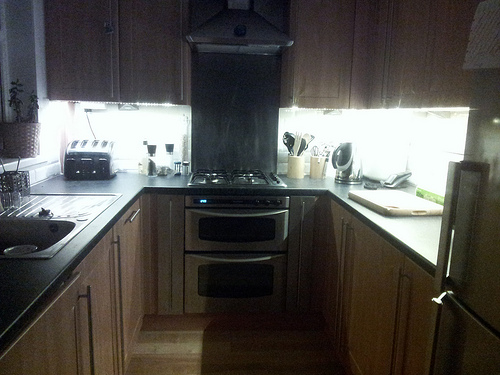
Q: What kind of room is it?
A: It is a kitchen.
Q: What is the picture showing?
A: It is showing a kitchen.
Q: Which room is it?
A: It is a kitchen.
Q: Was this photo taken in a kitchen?
A: Yes, it was taken in a kitchen.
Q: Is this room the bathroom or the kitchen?
A: It is the kitchen.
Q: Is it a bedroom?
A: No, it is a kitchen.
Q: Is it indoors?
A: Yes, it is indoors.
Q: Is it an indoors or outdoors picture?
A: It is indoors.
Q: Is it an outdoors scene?
A: No, it is indoors.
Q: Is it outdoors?
A: No, it is indoors.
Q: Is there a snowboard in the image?
A: No, there are no snowboards.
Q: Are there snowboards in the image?
A: No, there are no snowboards.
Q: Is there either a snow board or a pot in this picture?
A: No, there are no snowboards or pots.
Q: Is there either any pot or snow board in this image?
A: No, there are no snowboards or pots.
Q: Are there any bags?
A: No, there are no bags.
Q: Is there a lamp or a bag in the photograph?
A: No, there are no bags or lamps.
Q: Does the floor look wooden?
A: Yes, the floor is wooden.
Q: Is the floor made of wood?
A: Yes, the floor is made of wood.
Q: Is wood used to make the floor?
A: Yes, the floor is made of wood.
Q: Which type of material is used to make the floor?
A: The floor is made of wood.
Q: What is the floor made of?
A: The floor is made of wood.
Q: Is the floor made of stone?
A: No, the floor is made of wood.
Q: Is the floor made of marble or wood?
A: The floor is made of wood.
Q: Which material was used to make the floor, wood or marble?
A: The floor is made of wood.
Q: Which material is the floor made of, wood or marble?
A: The floor is made of wood.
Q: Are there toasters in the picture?
A: Yes, there is a toaster.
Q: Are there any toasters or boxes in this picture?
A: Yes, there is a toaster.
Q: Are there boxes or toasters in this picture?
A: Yes, there is a toaster.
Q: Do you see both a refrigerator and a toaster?
A: Yes, there are both a toaster and a refrigerator.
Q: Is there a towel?
A: No, there are no towels.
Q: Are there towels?
A: No, there are no towels.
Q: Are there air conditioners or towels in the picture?
A: No, there are no towels or air conditioners.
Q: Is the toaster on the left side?
A: Yes, the toaster is on the left of the image.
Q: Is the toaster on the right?
A: No, the toaster is on the left of the image.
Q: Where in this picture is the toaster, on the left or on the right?
A: The toaster is on the left of the image.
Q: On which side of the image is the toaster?
A: The toaster is on the left of the image.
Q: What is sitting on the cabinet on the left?
A: The toaster is sitting on the cabinet.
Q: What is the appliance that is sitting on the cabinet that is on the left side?
A: The appliance is a toaster.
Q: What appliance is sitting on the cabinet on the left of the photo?
A: The appliance is a toaster.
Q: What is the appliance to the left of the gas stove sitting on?
A: The toaster is sitting on the cabinet.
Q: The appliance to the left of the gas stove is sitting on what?
A: The toaster is sitting on the cabinet.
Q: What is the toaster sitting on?
A: The toaster is sitting on the cabinet.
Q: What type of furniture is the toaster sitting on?
A: The toaster is sitting on the cabinet.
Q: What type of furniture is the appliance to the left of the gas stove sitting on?
A: The toaster is sitting on the cabinet.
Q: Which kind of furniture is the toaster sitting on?
A: The toaster is sitting on the cabinet.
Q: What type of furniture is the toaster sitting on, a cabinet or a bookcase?
A: The toaster is sitting on a cabinet.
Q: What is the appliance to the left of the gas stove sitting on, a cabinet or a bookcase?
A: The toaster is sitting on a cabinet.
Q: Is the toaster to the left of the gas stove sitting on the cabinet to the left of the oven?
A: Yes, the toaster is sitting on the cabinet.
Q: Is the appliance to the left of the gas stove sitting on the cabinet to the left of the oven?
A: Yes, the toaster is sitting on the cabinet.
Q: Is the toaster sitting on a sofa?
A: No, the toaster is sitting on the cabinet.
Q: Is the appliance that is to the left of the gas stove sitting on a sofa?
A: No, the toaster is sitting on the cabinet.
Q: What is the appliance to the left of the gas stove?
A: The appliance is a toaster.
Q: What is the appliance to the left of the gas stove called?
A: The appliance is a toaster.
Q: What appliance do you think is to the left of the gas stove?
A: The appliance is a toaster.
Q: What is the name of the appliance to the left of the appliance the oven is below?
A: The appliance is a toaster.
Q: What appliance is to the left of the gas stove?
A: The appliance is a toaster.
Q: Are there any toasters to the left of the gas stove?
A: Yes, there is a toaster to the left of the gas stove.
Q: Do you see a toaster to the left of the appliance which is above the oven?
A: Yes, there is a toaster to the left of the gas stove.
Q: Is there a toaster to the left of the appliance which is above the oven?
A: Yes, there is a toaster to the left of the gas stove.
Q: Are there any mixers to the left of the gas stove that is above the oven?
A: No, there is a toaster to the left of the gas stove.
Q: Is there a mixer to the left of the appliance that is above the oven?
A: No, there is a toaster to the left of the gas stove.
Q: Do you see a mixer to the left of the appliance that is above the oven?
A: No, there is a toaster to the left of the gas stove.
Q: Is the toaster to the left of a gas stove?
A: Yes, the toaster is to the left of a gas stove.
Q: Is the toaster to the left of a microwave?
A: No, the toaster is to the left of a gas stove.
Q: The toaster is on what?
A: The toaster is on the counter.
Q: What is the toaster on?
A: The toaster is on the counter.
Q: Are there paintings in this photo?
A: No, there are no paintings.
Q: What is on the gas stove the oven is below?
A: The burner is on the gas stove.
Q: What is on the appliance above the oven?
A: The burner is on the gas stove.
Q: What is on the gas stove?
A: The burner is on the gas stove.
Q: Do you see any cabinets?
A: Yes, there is a cabinet.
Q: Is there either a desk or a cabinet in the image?
A: Yes, there is a cabinet.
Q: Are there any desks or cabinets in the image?
A: Yes, there is a cabinet.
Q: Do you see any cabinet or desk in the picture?
A: Yes, there is a cabinet.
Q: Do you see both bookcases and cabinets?
A: No, there is a cabinet but no bookcases.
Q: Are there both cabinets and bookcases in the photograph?
A: No, there is a cabinet but no bookcases.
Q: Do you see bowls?
A: No, there are no bowls.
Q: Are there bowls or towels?
A: No, there are no bowls or towels.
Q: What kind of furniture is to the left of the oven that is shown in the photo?
A: The piece of furniture is a cabinet.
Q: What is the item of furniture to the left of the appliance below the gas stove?
A: The piece of furniture is a cabinet.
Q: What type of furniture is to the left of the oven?
A: The piece of furniture is a cabinet.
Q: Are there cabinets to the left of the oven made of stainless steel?
A: Yes, there is a cabinet to the left of the oven.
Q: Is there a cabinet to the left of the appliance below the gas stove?
A: Yes, there is a cabinet to the left of the oven.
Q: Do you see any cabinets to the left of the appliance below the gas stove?
A: Yes, there is a cabinet to the left of the oven.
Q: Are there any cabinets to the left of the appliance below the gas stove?
A: Yes, there is a cabinet to the left of the oven.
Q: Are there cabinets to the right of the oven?
A: No, the cabinet is to the left of the oven.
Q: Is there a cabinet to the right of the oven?
A: No, the cabinet is to the left of the oven.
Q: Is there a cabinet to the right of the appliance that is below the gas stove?
A: No, the cabinet is to the left of the oven.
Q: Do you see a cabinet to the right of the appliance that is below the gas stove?
A: No, the cabinet is to the left of the oven.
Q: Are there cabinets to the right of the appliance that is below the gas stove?
A: No, the cabinet is to the left of the oven.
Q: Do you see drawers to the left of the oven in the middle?
A: No, there is a cabinet to the left of the oven.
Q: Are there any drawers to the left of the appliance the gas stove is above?
A: No, there is a cabinet to the left of the oven.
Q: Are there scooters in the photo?
A: No, there are no scooters.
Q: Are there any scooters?
A: No, there are no scooters.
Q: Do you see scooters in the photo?
A: No, there are no scooters.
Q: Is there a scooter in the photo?
A: No, there are no scooters.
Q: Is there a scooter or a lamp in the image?
A: No, there are no scooters or lamps.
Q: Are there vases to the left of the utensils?
A: Yes, there is a vase to the left of the utensils.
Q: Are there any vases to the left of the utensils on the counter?
A: Yes, there is a vase to the left of the utensils.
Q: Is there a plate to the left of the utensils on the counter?
A: No, there is a vase to the left of the utensils.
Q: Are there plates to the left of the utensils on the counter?
A: No, there is a vase to the left of the utensils.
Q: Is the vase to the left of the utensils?
A: Yes, the vase is to the left of the utensils.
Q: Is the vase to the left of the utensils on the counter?
A: Yes, the vase is to the left of the utensils.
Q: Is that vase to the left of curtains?
A: No, the vase is to the left of the utensils.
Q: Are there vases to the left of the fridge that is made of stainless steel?
A: Yes, there is a vase to the left of the refrigerator.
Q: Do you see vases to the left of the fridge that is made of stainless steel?
A: Yes, there is a vase to the left of the refrigerator.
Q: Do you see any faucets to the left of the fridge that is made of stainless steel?
A: No, there is a vase to the left of the fridge.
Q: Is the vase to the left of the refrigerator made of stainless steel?
A: Yes, the vase is to the left of the refrigerator.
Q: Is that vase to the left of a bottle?
A: No, the vase is to the left of the refrigerator.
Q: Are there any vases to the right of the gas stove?
A: Yes, there is a vase to the right of the gas stove.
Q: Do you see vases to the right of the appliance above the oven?
A: Yes, there is a vase to the right of the gas stove.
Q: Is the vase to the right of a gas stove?
A: Yes, the vase is to the right of a gas stove.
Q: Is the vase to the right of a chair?
A: No, the vase is to the right of a gas stove.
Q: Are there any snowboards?
A: No, there are no snowboards.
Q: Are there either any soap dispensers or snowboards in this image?
A: No, there are no snowboards or soap dispensers.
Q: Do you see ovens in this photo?
A: Yes, there is an oven.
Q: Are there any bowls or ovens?
A: Yes, there is an oven.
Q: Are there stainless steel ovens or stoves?
A: Yes, there is a stainless steel oven.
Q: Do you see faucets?
A: No, there are no faucets.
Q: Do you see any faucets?
A: No, there are no faucets.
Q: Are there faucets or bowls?
A: No, there are no faucets or bowls.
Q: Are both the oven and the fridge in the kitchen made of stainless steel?
A: Yes, both the oven and the freezer are made of stainless steel.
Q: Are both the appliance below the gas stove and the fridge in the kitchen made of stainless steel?
A: Yes, both the oven and the freezer are made of stainless steel.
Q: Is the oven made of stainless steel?
A: Yes, the oven is made of stainless steel.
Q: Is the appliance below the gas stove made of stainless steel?
A: Yes, the oven is made of stainless steel.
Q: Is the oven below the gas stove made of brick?
A: No, the oven is made of stainless steel.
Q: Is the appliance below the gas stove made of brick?
A: No, the oven is made of stainless steel.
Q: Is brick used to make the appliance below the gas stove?
A: No, the oven is made of stainless steel.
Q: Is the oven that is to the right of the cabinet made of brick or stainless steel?
A: The oven is made of stainless steel.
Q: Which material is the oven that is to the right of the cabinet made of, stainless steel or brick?
A: The oven is made of stainless steel.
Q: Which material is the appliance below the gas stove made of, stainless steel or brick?
A: The oven is made of stainless steel.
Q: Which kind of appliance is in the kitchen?
A: The appliance is an oven.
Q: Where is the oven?
A: The oven is in the kitchen.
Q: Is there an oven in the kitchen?
A: Yes, there is an oven in the kitchen.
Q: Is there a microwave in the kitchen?
A: No, there is an oven in the kitchen.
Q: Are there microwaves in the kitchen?
A: No, there is an oven in the kitchen.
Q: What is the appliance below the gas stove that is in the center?
A: The appliance is an oven.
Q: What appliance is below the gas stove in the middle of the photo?
A: The appliance is an oven.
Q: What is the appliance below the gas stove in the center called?
A: The appliance is an oven.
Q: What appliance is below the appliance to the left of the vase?
A: The appliance is an oven.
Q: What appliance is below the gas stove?
A: The appliance is an oven.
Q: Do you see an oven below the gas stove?
A: Yes, there is an oven below the gas stove.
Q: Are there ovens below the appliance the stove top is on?
A: Yes, there is an oven below the gas stove.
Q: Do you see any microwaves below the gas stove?
A: No, there is an oven below the gas stove.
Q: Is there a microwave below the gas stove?
A: No, there is an oven below the gas stove.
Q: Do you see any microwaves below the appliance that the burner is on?
A: No, there is an oven below the gas stove.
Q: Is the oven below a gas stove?
A: Yes, the oven is below a gas stove.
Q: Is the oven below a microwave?
A: No, the oven is below a gas stove.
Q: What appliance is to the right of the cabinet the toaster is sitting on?
A: The appliance is an oven.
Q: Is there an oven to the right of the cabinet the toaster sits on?
A: Yes, there is an oven to the right of the cabinet.